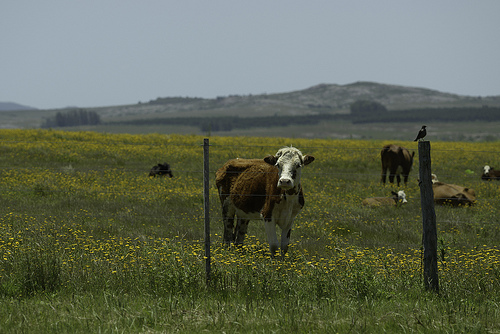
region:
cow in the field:
[198, 138, 331, 274]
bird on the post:
[412, 121, 428, 141]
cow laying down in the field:
[145, 157, 180, 186]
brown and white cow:
[361, 185, 409, 214]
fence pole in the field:
[196, 134, 214, 281]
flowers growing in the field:
[92, 228, 169, 273]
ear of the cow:
[263, 150, 276, 166]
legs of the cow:
[265, 231, 297, 258]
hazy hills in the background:
[311, 69, 416, 130]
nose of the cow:
[278, 176, 290, 187]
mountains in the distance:
[116, 61, 497, 135]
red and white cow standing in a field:
[215, 140, 329, 262]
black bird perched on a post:
[409, 122, 436, 141]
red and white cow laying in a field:
[475, 161, 498, 180]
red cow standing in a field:
[372, 134, 417, 190]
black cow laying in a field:
[139, 159, 185, 184]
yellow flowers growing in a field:
[73, 228, 146, 293]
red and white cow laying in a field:
[355, 184, 410, 214]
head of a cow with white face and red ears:
[261, 144, 316, 194]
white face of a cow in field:
[481, 158, 492, 178]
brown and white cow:
[212, 140, 312, 260]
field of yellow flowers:
[0, 123, 498, 305]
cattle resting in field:
[209, 123, 498, 258]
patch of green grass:
[0, 245, 498, 332]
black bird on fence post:
[414, 122, 431, 144]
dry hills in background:
[1, 78, 498, 133]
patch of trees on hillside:
[38, 106, 105, 128]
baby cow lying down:
[361, 186, 408, 211]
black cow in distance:
[147, 157, 172, 181]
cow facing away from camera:
[377, 140, 417, 188]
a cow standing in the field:
[172, 118, 324, 302]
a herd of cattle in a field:
[16, 125, 496, 259]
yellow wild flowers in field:
[0, 240, 499, 264]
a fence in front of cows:
[1, 126, 491, 323]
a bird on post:
[399, 103, 441, 150]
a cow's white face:
[275, 144, 303, 191]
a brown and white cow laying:
[341, 187, 412, 224]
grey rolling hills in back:
[0, 70, 499, 130]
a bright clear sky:
[0, 0, 497, 67]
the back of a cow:
[361, 137, 411, 187]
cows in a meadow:
[5, 3, 493, 324]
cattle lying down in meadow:
[356, 157, 496, 213]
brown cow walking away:
[373, 140, 418, 190]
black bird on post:
[412, 122, 431, 145]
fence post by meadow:
[414, 135, 445, 295]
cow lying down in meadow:
[145, 157, 178, 182]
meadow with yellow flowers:
[6, 128, 145, 286]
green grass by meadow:
[9, 295, 491, 323]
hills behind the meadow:
[3, 77, 494, 144]